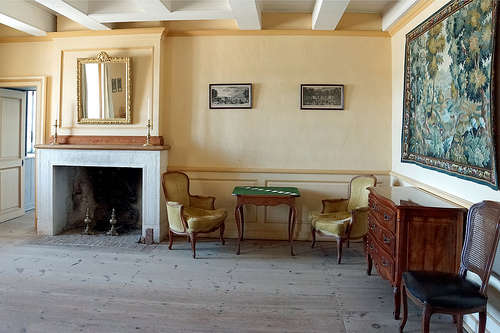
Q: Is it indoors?
A: Yes, it is indoors.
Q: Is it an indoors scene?
A: Yes, it is indoors.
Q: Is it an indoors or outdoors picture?
A: It is indoors.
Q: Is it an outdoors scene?
A: No, it is indoors.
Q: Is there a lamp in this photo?
A: No, there are no lamps.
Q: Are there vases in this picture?
A: No, there are no vases.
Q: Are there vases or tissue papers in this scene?
A: No, there are no vases or tissue papers.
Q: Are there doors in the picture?
A: Yes, there is a door.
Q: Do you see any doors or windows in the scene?
A: Yes, there is a door.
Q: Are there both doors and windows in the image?
A: No, there is a door but no windows.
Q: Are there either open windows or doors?
A: Yes, there is an open door.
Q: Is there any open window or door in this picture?
A: Yes, there is an open door.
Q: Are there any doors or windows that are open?
A: Yes, the door is open.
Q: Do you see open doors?
A: Yes, there is an open door.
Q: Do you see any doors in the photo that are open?
A: Yes, there is a door that is open.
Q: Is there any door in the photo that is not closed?
A: Yes, there is a open door.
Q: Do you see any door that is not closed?
A: Yes, there is a open door.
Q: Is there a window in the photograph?
A: No, there are no windows.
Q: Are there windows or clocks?
A: No, there are no windows or clocks.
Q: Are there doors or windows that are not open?
A: No, there is a door but it is open.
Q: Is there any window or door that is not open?
A: No, there is a door but it is open.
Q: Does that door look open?
A: Yes, the door is open.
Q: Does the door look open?
A: Yes, the door is open.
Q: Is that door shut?
A: No, the door is open.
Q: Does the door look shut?
A: No, the door is open.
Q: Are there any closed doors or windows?
A: No, there is a door but it is open.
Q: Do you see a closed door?
A: No, there is a door but it is open.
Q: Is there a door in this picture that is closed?
A: No, there is a door but it is open.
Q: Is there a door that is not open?
A: No, there is a door but it is open.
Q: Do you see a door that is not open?
A: No, there is a door but it is open.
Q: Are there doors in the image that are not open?
A: No, there is a door but it is open.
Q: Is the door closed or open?
A: The door is open.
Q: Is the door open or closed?
A: The door is open.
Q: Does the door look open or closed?
A: The door is open.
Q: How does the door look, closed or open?
A: The door is open.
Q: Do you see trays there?
A: No, there are no trays.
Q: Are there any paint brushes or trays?
A: No, there are no trays or paint brushes.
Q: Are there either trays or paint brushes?
A: No, there are no trays or paint brushes.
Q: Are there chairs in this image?
A: Yes, there is a chair.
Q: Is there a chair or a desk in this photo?
A: Yes, there is a chair.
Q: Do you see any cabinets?
A: No, there are no cabinets.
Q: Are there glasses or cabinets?
A: No, there are no cabinets or glasses.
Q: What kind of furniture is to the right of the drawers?
A: The piece of furniture is a chair.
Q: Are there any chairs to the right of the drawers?
A: Yes, there is a chair to the right of the drawers.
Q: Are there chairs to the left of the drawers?
A: No, the chair is to the right of the drawers.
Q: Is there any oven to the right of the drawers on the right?
A: No, there is a chair to the right of the drawers.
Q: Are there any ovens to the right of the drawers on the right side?
A: No, there is a chair to the right of the drawers.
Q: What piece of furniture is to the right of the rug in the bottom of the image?
A: The piece of furniture is a chair.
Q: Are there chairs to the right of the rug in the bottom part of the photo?
A: Yes, there is a chair to the right of the rug.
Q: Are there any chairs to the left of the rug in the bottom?
A: No, the chair is to the right of the rug.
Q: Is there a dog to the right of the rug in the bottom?
A: No, there is a chair to the right of the rug.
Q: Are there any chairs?
A: Yes, there is a chair.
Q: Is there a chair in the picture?
A: Yes, there is a chair.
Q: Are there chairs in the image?
A: Yes, there is a chair.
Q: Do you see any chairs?
A: Yes, there is a chair.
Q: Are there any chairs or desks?
A: Yes, there is a chair.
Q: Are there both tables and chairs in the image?
A: Yes, there are both a chair and a table.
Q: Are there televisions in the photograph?
A: No, there are no televisions.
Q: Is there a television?
A: No, there are no televisions.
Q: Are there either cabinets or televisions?
A: No, there are no televisions or cabinets.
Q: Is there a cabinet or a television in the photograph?
A: No, there are no televisions or cabinets.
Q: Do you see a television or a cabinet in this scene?
A: No, there are no televisions or cabinets.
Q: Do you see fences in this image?
A: No, there are no fences.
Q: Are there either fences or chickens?
A: No, there are no fences or chickens.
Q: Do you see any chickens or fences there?
A: No, there are no fences or chickens.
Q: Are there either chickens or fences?
A: No, there are no fences or chickens.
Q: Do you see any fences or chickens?
A: No, there are no fences or chickens.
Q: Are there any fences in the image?
A: No, there are no fences.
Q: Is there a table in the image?
A: Yes, there is a table.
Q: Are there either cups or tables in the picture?
A: Yes, there is a table.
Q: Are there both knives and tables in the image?
A: No, there is a table but no knives.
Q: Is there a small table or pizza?
A: Yes, there is a small table.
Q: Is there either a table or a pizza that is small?
A: Yes, the table is small.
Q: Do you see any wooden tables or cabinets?
A: Yes, there is a wood table.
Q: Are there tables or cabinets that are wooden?
A: Yes, the table is wooden.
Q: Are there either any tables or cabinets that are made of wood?
A: Yes, the table is made of wood.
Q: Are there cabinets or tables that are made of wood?
A: Yes, the table is made of wood.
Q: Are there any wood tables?
A: Yes, there is a wood table.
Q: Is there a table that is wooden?
A: Yes, there is a table that is wooden.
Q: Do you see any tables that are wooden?
A: Yes, there is a table that is wooden.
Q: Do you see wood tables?
A: Yes, there is a table that is made of wood.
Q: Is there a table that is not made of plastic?
A: Yes, there is a table that is made of wood.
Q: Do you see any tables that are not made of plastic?
A: Yes, there is a table that is made of wood.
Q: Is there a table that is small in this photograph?
A: Yes, there is a small table.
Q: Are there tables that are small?
A: Yes, there is a table that is small.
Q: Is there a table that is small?
A: Yes, there is a table that is small.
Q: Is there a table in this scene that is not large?
A: Yes, there is a small table.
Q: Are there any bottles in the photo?
A: No, there are no bottles.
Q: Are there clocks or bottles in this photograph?
A: No, there are no bottles or clocks.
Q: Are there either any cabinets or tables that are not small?
A: No, there is a table but it is small.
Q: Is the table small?
A: Yes, the table is small.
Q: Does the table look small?
A: Yes, the table is small.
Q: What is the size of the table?
A: The table is small.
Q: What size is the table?
A: The table is small.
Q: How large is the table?
A: The table is small.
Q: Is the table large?
A: No, the table is small.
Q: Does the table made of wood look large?
A: No, the table is small.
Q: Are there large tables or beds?
A: No, there is a table but it is small.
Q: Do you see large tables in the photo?
A: No, there is a table but it is small.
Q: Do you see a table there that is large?
A: No, there is a table but it is small.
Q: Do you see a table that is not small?
A: No, there is a table but it is small.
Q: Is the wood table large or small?
A: The table is small.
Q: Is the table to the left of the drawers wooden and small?
A: Yes, the table is wooden and small.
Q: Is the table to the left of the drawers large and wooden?
A: No, the table is wooden but small.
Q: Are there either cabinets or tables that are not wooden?
A: No, there is a table but it is wooden.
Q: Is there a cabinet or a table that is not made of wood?
A: No, there is a table but it is made of wood.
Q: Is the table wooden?
A: Yes, the table is wooden.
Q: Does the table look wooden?
A: Yes, the table is wooden.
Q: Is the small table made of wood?
A: Yes, the table is made of wood.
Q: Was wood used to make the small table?
A: Yes, the table is made of wood.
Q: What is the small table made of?
A: The table is made of wood.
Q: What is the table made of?
A: The table is made of wood.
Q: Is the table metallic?
A: No, the table is wooden.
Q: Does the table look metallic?
A: No, the table is wooden.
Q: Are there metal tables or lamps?
A: No, there is a table but it is wooden.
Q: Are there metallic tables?
A: No, there is a table but it is wooden.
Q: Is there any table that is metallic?
A: No, there is a table but it is wooden.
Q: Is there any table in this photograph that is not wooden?
A: No, there is a table but it is wooden.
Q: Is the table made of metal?
A: No, the table is made of wood.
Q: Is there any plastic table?
A: No, there is a table but it is made of wood.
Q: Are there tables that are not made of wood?
A: No, there is a table but it is made of wood.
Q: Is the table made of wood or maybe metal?
A: The table is made of wood.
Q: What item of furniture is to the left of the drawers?
A: The piece of furniture is a table.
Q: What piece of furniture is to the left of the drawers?
A: The piece of furniture is a table.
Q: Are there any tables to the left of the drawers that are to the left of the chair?
A: Yes, there is a table to the left of the drawers.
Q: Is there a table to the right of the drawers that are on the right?
A: No, the table is to the left of the drawers.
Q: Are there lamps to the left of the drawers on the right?
A: No, there is a table to the left of the drawers.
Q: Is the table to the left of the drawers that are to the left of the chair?
A: Yes, the table is to the left of the drawers.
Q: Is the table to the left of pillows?
A: No, the table is to the left of the drawers.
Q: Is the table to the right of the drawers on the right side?
A: No, the table is to the left of the drawers.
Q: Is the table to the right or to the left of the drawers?
A: The table is to the left of the drawers.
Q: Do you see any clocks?
A: No, there are no clocks.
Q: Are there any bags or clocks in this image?
A: No, there are no clocks or bags.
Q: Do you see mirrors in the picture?
A: Yes, there is a mirror.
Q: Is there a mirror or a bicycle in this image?
A: Yes, there is a mirror.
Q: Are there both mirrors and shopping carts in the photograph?
A: No, there is a mirror but no shopping carts.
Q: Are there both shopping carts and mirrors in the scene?
A: No, there is a mirror but no shopping carts.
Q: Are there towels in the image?
A: No, there are no towels.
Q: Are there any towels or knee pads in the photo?
A: No, there are no towels or knee pads.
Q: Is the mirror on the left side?
A: Yes, the mirror is on the left of the image.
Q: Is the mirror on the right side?
A: No, the mirror is on the left of the image.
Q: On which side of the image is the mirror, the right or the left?
A: The mirror is on the left of the image.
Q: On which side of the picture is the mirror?
A: The mirror is on the left of the image.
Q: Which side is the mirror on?
A: The mirror is on the left of the image.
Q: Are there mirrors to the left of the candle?
A: Yes, there is a mirror to the left of the candle.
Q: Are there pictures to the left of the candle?
A: No, there is a mirror to the left of the candle.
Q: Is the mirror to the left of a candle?
A: Yes, the mirror is to the left of a candle.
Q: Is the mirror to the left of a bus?
A: No, the mirror is to the left of a candle.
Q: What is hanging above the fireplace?
A: The mirror is hanging above the fireplace.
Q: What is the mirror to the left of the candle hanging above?
A: The mirror is hanging above the fireplace.